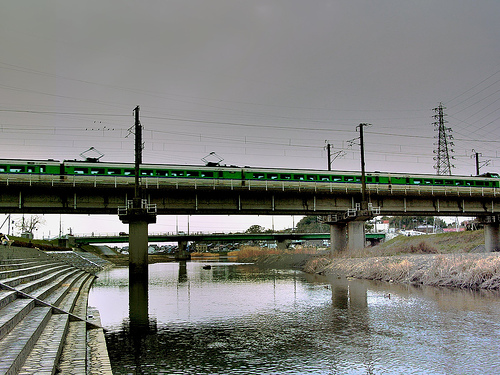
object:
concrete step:
[87, 327, 113, 375]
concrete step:
[0, 298, 37, 337]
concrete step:
[20, 312, 70, 374]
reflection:
[103, 313, 322, 373]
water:
[87, 256, 500, 374]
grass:
[300, 252, 500, 290]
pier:
[128, 221, 150, 281]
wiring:
[0, 108, 136, 117]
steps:
[0, 289, 19, 310]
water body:
[156, 286, 355, 363]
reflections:
[348, 285, 366, 310]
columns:
[328, 224, 346, 253]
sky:
[0, 1, 500, 249]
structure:
[22, 230, 34, 239]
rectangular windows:
[73, 166, 88, 175]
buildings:
[416, 222, 432, 235]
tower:
[430, 102, 455, 175]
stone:
[86, 313, 95, 318]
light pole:
[357, 121, 367, 208]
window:
[200, 169, 215, 177]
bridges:
[0, 173, 500, 262]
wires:
[444, 71, 499, 104]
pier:
[346, 219, 365, 257]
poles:
[134, 106, 141, 190]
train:
[0, 158, 500, 188]